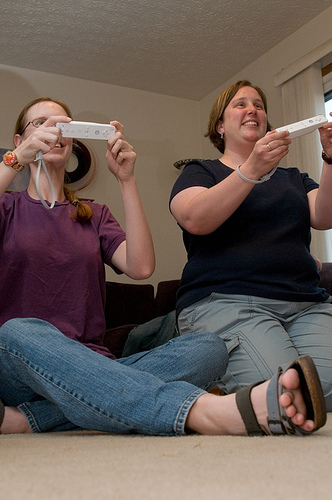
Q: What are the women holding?
A: Game controllers.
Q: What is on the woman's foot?
A: A sandal.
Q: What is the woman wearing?
A: A purple shirt.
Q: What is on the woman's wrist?
A: A watch.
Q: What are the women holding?
A: Remotes.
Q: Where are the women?
A: In a room.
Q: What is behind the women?
A: A wall.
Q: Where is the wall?
A: Behind the women.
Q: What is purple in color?
A: Shirt.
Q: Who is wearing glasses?
A: The woman.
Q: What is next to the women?
A: Window.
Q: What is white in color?
A: Remote.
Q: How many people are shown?
A: Two.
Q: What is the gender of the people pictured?
A: Female.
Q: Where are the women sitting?
A: On the carpet.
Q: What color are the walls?
A: Beige.